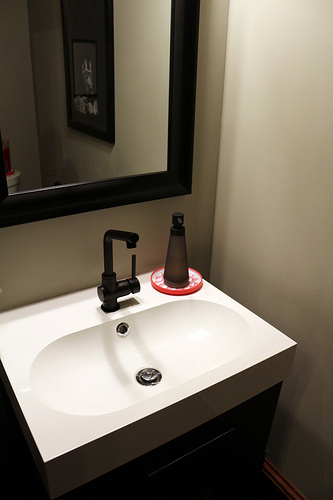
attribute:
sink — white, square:
[4, 262, 297, 467]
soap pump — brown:
[160, 214, 192, 287]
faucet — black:
[94, 226, 173, 294]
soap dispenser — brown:
[163, 211, 191, 288]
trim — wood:
[261, 456, 308, 498]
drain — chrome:
[134, 364, 163, 388]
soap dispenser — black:
[160, 213, 194, 288]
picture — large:
[55, 3, 128, 147]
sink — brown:
[38, 432, 207, 484]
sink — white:
[3, 269, 296, 494]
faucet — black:
[96, 223, 144, 307]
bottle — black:
[162, 211, 189, 287]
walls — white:
[258, 21, 323, 159]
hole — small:
[118, 357, 185, 402]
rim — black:
[98, 161, 217, 203]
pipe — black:
[96, 238, 132, 318]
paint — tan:
[16, 236, 95, 286]